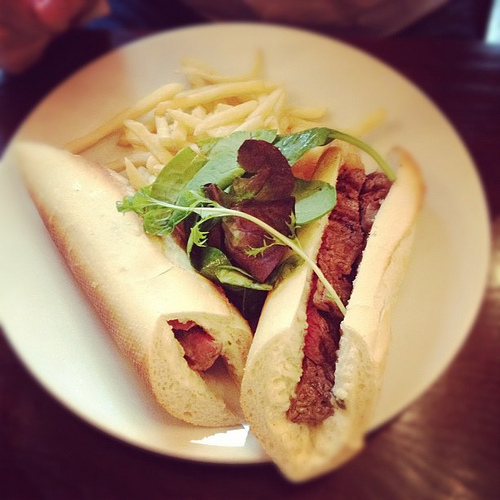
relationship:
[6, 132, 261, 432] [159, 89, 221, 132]
sandwhich and french fries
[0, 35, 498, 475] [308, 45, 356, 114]
plate round and white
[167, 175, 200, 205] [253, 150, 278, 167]
green and purple lettuce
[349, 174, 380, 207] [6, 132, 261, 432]
brown meat in sandwhich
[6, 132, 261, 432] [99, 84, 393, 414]
sandwhich for lunch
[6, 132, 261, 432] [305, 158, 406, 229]
sandwhich in pieces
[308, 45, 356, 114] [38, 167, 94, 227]
white roll of bread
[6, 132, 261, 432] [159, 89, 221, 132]
sandwhich salad and fries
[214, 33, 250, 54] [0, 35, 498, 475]
light on plate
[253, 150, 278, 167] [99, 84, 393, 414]
lettuce on food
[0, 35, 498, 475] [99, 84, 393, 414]
plate of food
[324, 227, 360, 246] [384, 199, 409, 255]
meat on bun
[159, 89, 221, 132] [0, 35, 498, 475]
fries on plate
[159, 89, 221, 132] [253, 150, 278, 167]
fries and lettuce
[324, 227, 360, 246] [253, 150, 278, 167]
meat and lettuce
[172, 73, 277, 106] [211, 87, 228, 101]
fry thin and yellow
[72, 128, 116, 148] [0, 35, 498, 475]
frie over plate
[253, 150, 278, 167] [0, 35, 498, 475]
lettuce on plate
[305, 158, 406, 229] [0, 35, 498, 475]
hotdog served over plate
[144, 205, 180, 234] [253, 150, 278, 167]
leaf of lettuce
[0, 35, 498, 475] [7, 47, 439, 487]
plate of lunch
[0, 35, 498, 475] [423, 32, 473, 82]
plate over table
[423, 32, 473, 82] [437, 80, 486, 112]
table made of wood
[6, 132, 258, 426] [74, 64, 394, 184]
sandwhich with french fries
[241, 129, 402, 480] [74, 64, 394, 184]
sandwhich with french fries